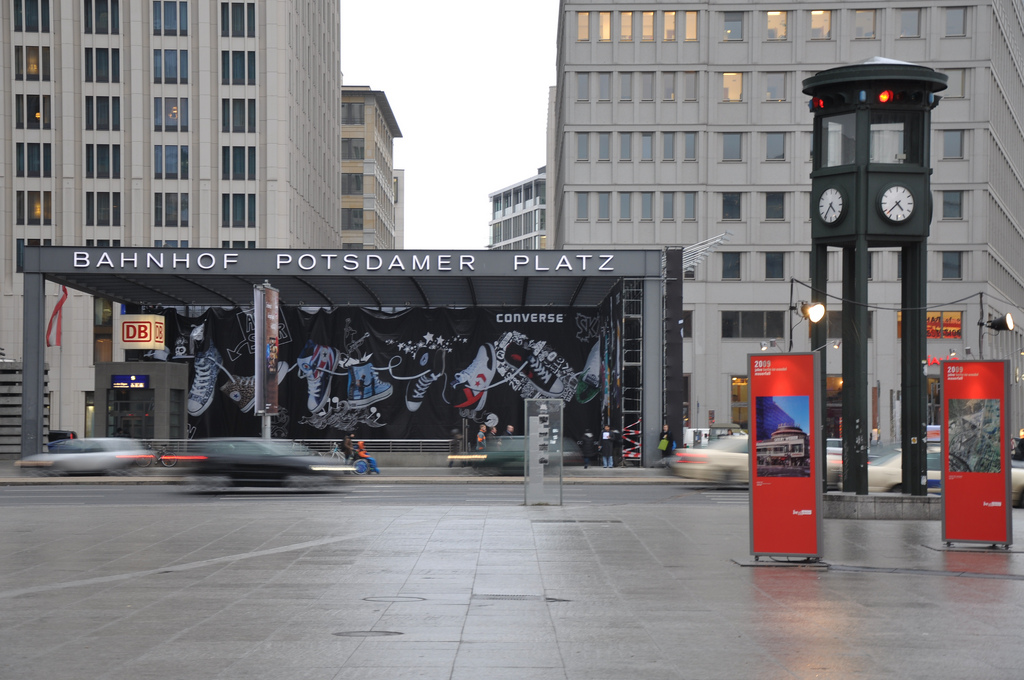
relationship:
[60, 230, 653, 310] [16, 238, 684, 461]
word on structure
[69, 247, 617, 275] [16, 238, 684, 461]
word on structure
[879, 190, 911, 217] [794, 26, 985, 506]
clock positioned forward on monument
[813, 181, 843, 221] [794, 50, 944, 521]
clock positioned on monument